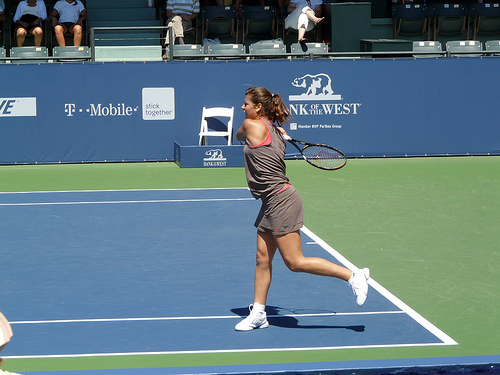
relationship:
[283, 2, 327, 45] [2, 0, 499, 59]
spectator in bleachers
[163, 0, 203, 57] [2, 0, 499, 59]
spectator in bleachers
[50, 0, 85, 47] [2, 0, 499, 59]
spectator in bleachers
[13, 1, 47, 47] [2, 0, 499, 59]
fans in bleachers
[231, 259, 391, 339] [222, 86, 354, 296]
shoes on girl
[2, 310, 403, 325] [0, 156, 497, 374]
line on court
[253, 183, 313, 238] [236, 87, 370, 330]
gray shorts of girl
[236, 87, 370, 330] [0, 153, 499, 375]
girl on a court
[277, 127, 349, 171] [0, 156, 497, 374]
racket on a court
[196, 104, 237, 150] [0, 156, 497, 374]
chair on a court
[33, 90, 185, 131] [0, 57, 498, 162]
words on a banner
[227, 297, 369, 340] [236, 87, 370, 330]
shadow of a girl